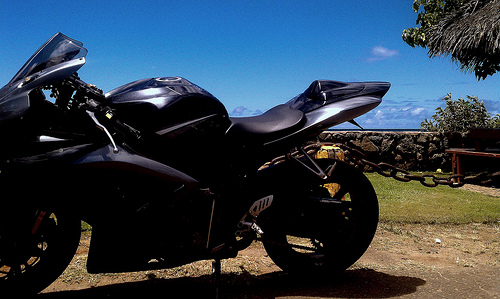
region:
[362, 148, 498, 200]
chain barrier behind the bike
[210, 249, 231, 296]
kickstand on the bike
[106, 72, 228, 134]
gas tank on the bike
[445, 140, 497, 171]
brown table by the wall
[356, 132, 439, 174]
stone wall behind the bike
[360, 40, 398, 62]
white cloud in blue sky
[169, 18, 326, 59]
bright blue sky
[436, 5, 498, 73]
thatch roof over table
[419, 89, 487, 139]
bush by the wall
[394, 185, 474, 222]
grass behind the bike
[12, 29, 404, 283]
nice motorcycle parked outside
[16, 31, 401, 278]
dark motorcycle parked outside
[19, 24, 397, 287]
nice dark motorcycle parked outside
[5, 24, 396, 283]
black motorcycle parked outside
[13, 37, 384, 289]
nice black motorcycle parked outside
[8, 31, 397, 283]
nice shiny motorcycle parked outside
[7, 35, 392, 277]
beautiful motorcycle parked outside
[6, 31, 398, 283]
clean motorcycle parked outside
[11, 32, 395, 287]
polished motorcycle parked outside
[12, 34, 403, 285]
well kept motorcycle parked outside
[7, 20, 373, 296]
the motorcycle is black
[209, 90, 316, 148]
the seat is black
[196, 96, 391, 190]
the seat is black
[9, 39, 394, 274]
this is a motorbike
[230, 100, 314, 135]
the seat is black in color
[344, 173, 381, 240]
this is the wheel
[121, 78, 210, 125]
this is the engine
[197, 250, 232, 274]
this is the stand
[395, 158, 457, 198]
this is a chain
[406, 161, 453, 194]
the chain is big in size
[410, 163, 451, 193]
the chain is metallic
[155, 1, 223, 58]
the sky is blue in color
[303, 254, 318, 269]
part of a wheel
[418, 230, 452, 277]
part of a ground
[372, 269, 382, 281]
part fo a shade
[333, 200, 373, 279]
part of a wheel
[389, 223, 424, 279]
part of af loor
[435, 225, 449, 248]
part of a ground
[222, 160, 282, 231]
part of a metal